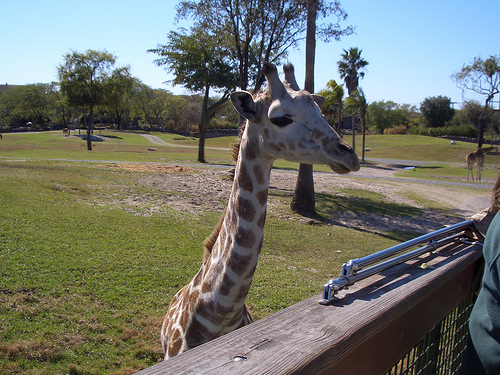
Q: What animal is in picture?
A: Giraffe.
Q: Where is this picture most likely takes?
A: Zoo.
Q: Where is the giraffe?
A: Behind fence.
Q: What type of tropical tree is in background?
A: Palm tree.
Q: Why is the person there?
A: Looking at giraffe.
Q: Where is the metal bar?
A: On the fence rail.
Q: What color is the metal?
A: Silver.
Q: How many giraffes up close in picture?
A: One.